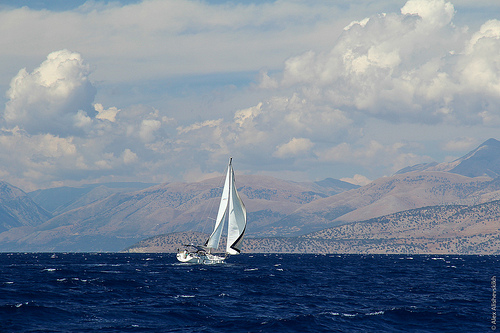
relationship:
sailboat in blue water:
[167, 133, 302, 308] [0, 252, 500, 333]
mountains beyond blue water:
[327, 164, 441, 251] [0, 252, 500, 333]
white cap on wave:
[48, 267, 58, 271] [15, 257, 100, 302]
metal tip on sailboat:
[227, 154, 234, 168] [175, 156, 248, 266]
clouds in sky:
[6, 1, 498, 185] [1, 1, 498, 190]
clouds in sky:
[170, 95, 291, 162] [17, 10, 497, 154]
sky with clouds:
[1, 1, 498, 190] [8, 5, 495, 135]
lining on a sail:
[193, 173, 330, 267] [186, 169, 298, 257]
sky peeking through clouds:
[186, 47, 264, 121] [288, 82, 394, 165]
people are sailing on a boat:
[175, 242, 208, 256] [160, 98, 274, 312]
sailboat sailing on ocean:
[175, 156, 248, 266] [0, 254, 497, 331]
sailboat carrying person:
[175, 156, 248, 266] [179, 249, 189, 262]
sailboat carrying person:
[175, 156, 248, 266] [188, 251, 193, 260]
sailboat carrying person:
[175, 156, 248, 266] [175, 249, 179, 257]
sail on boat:
[225, 166, 247, 256] [168, 241, 226, 266]